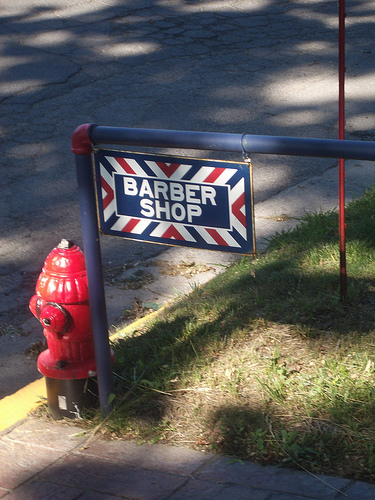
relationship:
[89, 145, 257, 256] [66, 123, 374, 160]
sign hanging from pole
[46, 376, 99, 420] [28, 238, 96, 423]
bottom black base of a fire fire hydrant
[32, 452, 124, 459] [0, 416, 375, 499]
brick concrete floor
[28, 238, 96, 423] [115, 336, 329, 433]
fire hydrant in grass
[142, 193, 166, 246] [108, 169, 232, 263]
sh letters in shop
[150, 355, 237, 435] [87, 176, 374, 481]
part of grass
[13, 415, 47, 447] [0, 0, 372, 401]
edge of a road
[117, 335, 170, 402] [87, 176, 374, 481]
part of a lawn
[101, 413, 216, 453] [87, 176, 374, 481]
edge of a lawn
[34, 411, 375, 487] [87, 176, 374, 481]
edge of a lawn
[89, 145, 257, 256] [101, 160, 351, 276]
sign indicating presence of a barber shop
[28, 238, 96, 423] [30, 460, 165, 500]
fire hydrant near sidewalk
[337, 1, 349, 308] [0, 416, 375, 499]
pole in a floor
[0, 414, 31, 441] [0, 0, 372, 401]
edge separating sidewalk from road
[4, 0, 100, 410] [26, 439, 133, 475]
road at left of sidewalk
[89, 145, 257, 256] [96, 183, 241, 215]
sign says "barber shop"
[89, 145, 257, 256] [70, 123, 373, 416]
sign hanging from railing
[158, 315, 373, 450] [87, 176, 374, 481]
light shining on grass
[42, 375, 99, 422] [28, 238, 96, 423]
bottom of hydrant